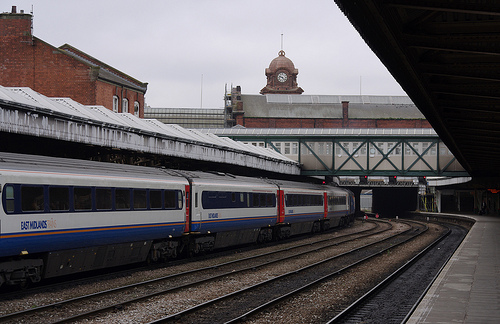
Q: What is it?
A: Train.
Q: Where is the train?
A: On the tracks.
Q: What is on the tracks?
A: Train.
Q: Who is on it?
A: People.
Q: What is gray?
A: The sky.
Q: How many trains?
A: 1.